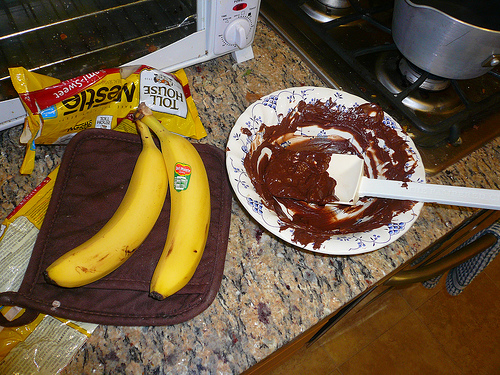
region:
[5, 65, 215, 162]
a plastic bag of Nestle chocolate chips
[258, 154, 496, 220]
a white plastic spatula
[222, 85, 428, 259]
a white plate with blue stylized pattern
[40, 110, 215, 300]
a pair of ripe bananas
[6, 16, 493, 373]
a multicolored marble countertop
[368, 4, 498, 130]
a blue metal cook pot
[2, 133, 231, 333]
a dark brown pot holder with a hanging loop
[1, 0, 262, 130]
a white microwave oven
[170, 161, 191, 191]
a red and green banana label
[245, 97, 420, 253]
dark chocolate cake frosting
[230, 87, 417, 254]
paper plate with melted chocolate in it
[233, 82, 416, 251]
blue pattern on white paper plate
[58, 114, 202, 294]
bananas laying on brown oven mitt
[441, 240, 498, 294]
towel hanging on handle bar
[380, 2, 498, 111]
silver pot on black stove burner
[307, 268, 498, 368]
flooring in front of cabinets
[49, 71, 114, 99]
white lettering on red background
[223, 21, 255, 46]
white knob on conventional oven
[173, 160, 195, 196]
sticker on yellow banana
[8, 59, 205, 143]
yellow and red plastic bag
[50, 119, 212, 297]
two yellow bananas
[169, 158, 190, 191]
green, white, red sticker on bananas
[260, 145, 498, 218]
white spatula covered in chocolate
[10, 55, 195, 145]
bag of chocolate chips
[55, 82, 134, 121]
black lettering on yellow bag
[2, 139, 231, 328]
brown oven mitt on corner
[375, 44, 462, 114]
black burner on stove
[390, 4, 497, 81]
silver pot sitting on black burner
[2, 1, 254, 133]
conventional oven on countertop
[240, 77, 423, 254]
paper plate covered in melted chocolate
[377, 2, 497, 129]
metal pan on burner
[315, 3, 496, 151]
burner of gas stove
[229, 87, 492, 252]
white spatula on plate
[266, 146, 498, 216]
chocolate on white spatula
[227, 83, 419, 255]
chocolate on plate with design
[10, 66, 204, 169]
yellow bag with torn top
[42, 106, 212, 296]
two bananas with yellow skin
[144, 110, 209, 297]
sticker on banana skin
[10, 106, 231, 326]
bananas on brown pot holder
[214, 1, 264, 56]
dial on white surface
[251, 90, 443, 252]
There is icing on the plate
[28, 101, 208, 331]
The bananas are yellow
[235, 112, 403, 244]
the icing is brown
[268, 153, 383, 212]
The spreader is white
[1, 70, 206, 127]
the bag is yellow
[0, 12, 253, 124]
The microwave oven is white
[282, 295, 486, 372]
the ground is brown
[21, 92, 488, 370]
The countertop is made of marble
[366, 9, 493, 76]
the pot is silver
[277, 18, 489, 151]
the stove is a gas stove